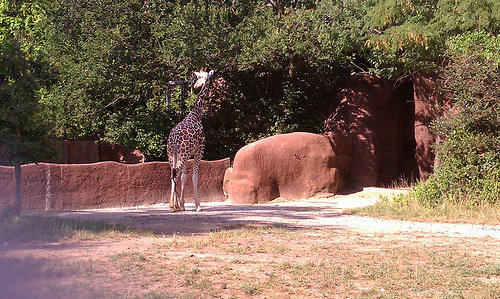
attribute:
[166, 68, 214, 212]
giraffe — facing, tall, standing, brown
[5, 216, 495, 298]
grass — scattered, green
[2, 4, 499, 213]
forest — green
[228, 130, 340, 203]
wall — curved, rocky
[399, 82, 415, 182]
gate — brown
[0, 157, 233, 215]
fence — rectangular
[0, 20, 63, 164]
tree — casting a shadow, growing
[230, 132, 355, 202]
rock — large, brown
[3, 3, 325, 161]
bush — thick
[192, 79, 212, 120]
neck — giraffe's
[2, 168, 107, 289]
dust — stirring up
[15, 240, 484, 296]
grass — dry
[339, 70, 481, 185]
wall — shadowed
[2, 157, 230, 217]
wall — retaining, brown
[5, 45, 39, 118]
leaves — gree